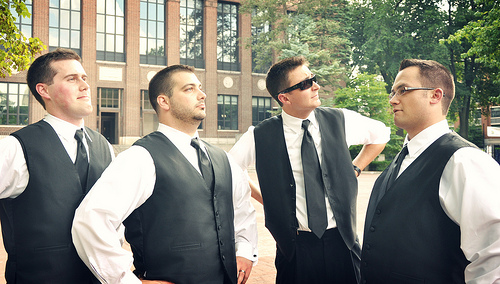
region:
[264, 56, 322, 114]
Man wearing black sunglasses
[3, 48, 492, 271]
Four men wearing black ties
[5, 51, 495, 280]
Four men wearing black vests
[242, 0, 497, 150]
Green trees in background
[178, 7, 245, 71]
Reflection of tree in window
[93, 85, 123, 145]
Open door of building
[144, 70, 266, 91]
White circles on building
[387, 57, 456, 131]
Man with glasses looking at other men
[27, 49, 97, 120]
Man with short brown hair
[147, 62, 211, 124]
Man with short hair and goatee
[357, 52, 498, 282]
a man wearing a vest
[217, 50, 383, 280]
a man wearing a sunglass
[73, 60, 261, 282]
a man in black vest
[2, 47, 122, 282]
a man in black vest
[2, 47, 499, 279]
four men in black vest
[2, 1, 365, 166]
a large building in the background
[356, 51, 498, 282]
a man wearing an eye glass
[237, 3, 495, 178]
trees are in the background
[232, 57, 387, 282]
a man with a tie and vest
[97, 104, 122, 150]
the entrance door for the building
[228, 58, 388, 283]
a guy resting his palms on his hip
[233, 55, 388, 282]
the guy is taking a look on his left side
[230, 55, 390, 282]
guy with a black tie on his white shirt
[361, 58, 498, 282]
a guy wearing his eye glasses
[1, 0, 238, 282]
two guys standing in front of a building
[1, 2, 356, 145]
branches of tress covering partially the right and left side of the building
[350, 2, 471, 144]
trees with leaves covering the sky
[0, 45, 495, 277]
four people standing besides one another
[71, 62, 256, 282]
a guy wearing a ring in the left hand middle finger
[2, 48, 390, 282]
three guys are looking in the same direction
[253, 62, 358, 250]
this is a man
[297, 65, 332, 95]
this is a spectacle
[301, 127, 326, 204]
this is a necktie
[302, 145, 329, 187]
the tie is black in color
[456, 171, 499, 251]
this is a shirt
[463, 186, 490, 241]
the shirt is white in color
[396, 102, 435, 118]
the man is light skinned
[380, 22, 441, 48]
this is a tree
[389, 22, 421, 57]
the leaves are green in color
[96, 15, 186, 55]
this is a building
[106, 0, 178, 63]
the house has windows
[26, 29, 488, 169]
the men are standing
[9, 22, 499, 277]
they are wearing black suits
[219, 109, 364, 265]
the jacket is open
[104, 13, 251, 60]
the windows are closed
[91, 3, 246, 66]
the house has windows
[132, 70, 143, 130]
the wall is brown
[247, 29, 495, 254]
the men are wearing spectaces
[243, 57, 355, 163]
the spectacles are dark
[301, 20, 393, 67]
the trees are green in colour